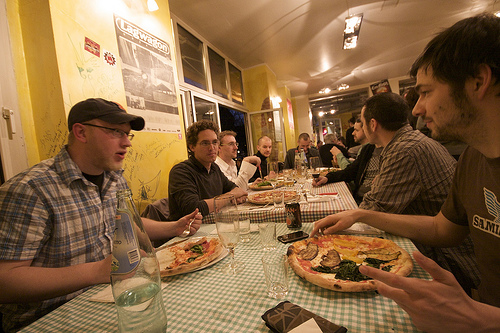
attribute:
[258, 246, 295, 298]
glass — empty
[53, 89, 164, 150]
hat — green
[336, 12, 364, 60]
light — large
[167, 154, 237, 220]
sweater — black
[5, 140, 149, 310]
shirt — plaid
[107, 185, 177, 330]
bottle — big, half-filled, glass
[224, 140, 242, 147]
glasses — black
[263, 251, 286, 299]
glass — empty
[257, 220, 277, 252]
glass — empty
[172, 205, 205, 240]
hand — man's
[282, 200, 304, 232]
can — beverage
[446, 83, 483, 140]
beard — man's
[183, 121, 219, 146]
hair — brown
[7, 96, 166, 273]
person — man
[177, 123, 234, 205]
person — man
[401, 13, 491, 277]
person — man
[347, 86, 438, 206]
person — man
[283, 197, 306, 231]
drink — small, soda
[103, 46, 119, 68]
picture — small, red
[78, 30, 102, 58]
picture — small, red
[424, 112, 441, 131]
moustache — man's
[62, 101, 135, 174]
head — man's